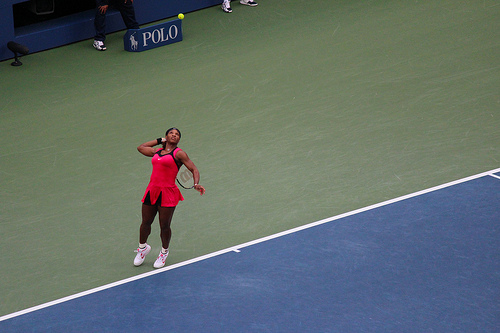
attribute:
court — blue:
[0, 169, 499, 331]